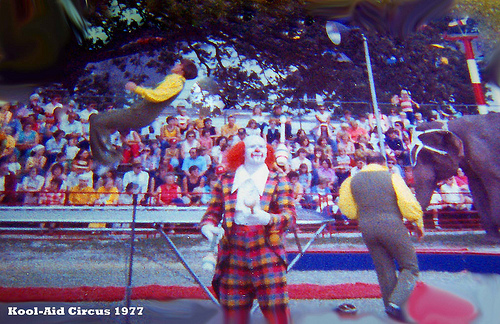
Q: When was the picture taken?
A: 1977.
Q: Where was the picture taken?
A: Kool-Aid Circus.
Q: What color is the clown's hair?
A: Red.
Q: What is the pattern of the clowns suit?
A: Plaid.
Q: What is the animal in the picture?
A: Elephant.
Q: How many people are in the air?
A: 1.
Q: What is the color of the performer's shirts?
A: Yellow.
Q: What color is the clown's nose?
A: Red.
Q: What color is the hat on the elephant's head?
A: White.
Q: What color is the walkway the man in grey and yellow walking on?
A: Red.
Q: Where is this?
A: At the circus.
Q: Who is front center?
A: A clown.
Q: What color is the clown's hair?
A: Red.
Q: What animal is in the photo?
A: Elephant.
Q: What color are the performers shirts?
A: Yellow.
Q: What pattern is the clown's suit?
A: Plaid.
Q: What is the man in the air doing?
A: A flip.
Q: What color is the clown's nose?
A: Red.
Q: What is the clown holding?
A: A microphone.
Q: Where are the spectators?
A: Sitting in the stands.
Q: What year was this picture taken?
A: 1977.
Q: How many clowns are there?
A: One.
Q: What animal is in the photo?
A: Elephant.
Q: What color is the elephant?
A: Gray.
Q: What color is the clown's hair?
A: Orange.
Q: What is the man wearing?
A: A clown costume.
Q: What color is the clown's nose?
A: Red.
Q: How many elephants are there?
A: One.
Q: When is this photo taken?
A: During a circus.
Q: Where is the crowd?
A: Behind the circus.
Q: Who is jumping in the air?
A: A man.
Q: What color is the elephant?
A: Gray.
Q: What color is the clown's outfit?
A: Plaid.